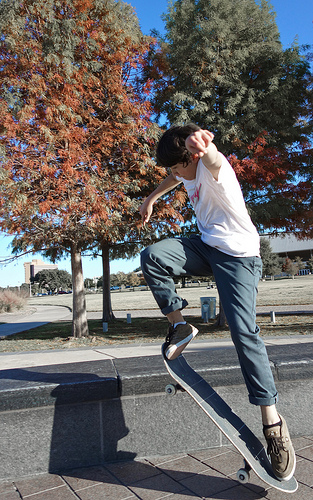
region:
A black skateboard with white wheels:
[151, 322, 300, 498]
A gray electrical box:
[188, 292, 219, 330]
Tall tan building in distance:
[15, 253, 64, 302]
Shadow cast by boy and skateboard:
[5, 357, 271, 498]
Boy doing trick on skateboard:
[136, 122, 305, 485]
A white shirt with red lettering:
[178, 150, 260, 261]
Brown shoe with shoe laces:
[250, 418, 302, 492]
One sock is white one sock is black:
[170, 318, 302, 477]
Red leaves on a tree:
[32, 196, 120, 234]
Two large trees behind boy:
[2, 0, 309, 330]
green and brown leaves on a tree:
[5, 4, 157, 191]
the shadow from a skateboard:
[88, 458, 263, 498]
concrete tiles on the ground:
[34, 477, 92, 498]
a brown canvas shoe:
[260, 414, 297, 480]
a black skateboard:
[156, 355, 295, 496]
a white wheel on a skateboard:
[230, 464, 255, 488]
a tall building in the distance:
[20, 259, 58, 290]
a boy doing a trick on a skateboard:
[122, 121, 292, 492]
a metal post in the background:
[195, 293, 216, 326]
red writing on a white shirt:
[182, 181, 212, 214]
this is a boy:
[110, 109, 253, 354]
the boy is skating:
[158, 264, 259, 498]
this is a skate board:
[189, 380, 228, 419]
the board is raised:
[164, 353, 236, 492]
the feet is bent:
[159, 308, 199, 361]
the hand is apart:
[181, 126, 224, 167]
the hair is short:
[162, 135, 180, 161]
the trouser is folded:
[253, 393, 277, 404]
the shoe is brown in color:
[174, 330, 189, 338]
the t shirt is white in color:
[211, 204, 236, 230]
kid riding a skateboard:
[112, 108, 261, 358]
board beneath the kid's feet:
[158, 352, 284, 483]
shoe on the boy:
[254, 414, 301, 481]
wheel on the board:
[226, 458, 252, 494]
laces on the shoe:
[262, 425, 291, 464]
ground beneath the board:
[133, 456, 187, 491]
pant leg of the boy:
[207, 255, 293, 411]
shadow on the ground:
[47, 368, 145, 480]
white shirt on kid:
[193, 166, 243, 232]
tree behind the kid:
[47, 156, 113, 250]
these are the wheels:
[153, 370, 205, 409]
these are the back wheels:
[234, 447, 261, 487]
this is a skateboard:
[151, 337, 307, 495]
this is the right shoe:
[153, 317, 200, 364]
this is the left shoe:
[257, 409, 300, 486]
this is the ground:
[0, 430, 312, 498]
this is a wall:
[7, 352, 311, 473]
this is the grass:
[29, 330, 57, 346]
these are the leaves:
[106, 324, 144, 339]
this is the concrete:
[33, 414, 66, 445]